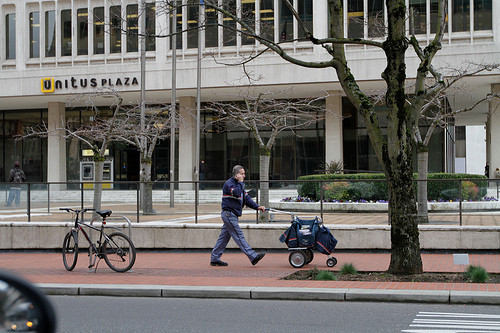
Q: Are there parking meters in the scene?
A: No, there are no parking meters.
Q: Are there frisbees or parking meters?
A: No, there are no parking meters or frisbees.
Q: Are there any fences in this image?
A: Yes, there is a fence.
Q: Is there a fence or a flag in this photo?
A: Yes, there is a fence.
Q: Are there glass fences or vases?
A: Yes, there is a glass fence.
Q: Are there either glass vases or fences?
A: Yes, there is a glass fence.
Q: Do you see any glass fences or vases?
A: Yes, there is a glass fence.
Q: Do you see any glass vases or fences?
A: Yes, there is a glass fence.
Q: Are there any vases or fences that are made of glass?
A: Yes, the fence is made of glass.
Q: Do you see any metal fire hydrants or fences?
A: Yes, there is a metal fence.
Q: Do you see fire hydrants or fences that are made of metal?
A: Yes, the fence is made of metal.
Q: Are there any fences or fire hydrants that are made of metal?
A: Yes, the fence is made of metal.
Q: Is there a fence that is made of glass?
A: Yes, there is a fence that is made of glass.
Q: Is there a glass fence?
A: Yes, there is a fence that is made of glass.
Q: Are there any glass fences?
A: Yes, there is a fence that is made of glass.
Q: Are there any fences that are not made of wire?
A: Yes, there is a fence that is made of glass.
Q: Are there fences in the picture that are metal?
A: Yes, there is a metal fence.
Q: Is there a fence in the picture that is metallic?
A: Yes, there is a fence that is metallic.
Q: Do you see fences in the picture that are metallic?
A: Yes, there is a fence that is metallic.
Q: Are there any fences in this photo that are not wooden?
A: Yes, there is a metallic fence.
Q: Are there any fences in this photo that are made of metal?
A: Yes, there is a fence that is made of metal.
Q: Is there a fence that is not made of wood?
A: Yes, there is a fence that is made of metal.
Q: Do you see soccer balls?
A: No, there are no soccer balls.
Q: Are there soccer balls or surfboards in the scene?
A: No, there are no soccer balls or surfboards.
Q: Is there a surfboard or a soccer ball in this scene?
A: No, there are no soccer balls or surfboards.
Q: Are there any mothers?
A: No, there are no mothers.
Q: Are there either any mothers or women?
A: No, there are no mothers or women.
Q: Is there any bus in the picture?
A: No, there are no buses.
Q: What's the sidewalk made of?
A: The sidewalk is made of brick.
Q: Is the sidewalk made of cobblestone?
A: No, the sidewalk is made of brick.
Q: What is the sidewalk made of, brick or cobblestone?
A: The sidewalk is made of brick.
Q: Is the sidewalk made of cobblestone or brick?
A: The sidewalk is made of brick.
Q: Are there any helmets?
A: No, there are no helmets.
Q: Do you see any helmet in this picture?
A: No, there are no helmets.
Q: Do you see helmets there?
A: No, there are no helmets.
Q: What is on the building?
A: The sign is on the building.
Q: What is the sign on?
A: The sign is on the building.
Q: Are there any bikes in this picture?
A: Yes, there is a bike.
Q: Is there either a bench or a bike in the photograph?
A: Yes, there is a bike.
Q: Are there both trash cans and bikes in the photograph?
A: No, there is a bike but no trash cans.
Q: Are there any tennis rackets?
A: No, there are no tennis rackets.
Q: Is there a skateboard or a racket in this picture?
A: No, there are no rackets or skateboards.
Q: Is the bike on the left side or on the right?
A: The bike is on the left of the image.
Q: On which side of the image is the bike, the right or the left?
A: The bike is on the left of the image.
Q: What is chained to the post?
A: The bike is chained to the post.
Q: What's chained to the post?
A: The bike is chained to the post.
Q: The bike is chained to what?
A: The bike is chained to the post.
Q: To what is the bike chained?
A: The bike is chained to the post.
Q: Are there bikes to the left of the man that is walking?
A: Yes, there is a bike to the left of the man.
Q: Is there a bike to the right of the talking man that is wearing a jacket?
A: No, the bike is to the left of the man.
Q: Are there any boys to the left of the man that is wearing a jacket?
A: No, there is a bike to the left of the man.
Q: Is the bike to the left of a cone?
A: No, the bike is to the left of the man.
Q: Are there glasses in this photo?
A: No, there are no glasses.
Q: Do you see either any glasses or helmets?
A: No, there are no glasses or helmets.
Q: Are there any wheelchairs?
A: No, there are no wheelchairs.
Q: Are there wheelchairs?
A: No, there are no wheelchairs.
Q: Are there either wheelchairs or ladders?
A: No, there are no wheelchairs or ladders.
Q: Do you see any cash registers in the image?
A: No, there are no cash registers.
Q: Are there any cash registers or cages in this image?
A: No, there are no cash registers or cages.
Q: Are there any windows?
A: Yes, there are windows.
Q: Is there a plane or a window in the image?
A: Yes, there are windows.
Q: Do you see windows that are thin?
A: Yes, there are thin windows.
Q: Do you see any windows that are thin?
A: Yes, there are windows that are thin.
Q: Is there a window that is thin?
A: Yes, there are windows that are thin.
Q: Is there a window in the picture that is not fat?
A: Yes, there are thin windows.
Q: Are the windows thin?
A: Yes, the windows are thin.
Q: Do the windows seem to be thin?
A: Yes, the windows are thin.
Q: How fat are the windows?
A: The windows are thin.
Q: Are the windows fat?
A: No, the windows are thin.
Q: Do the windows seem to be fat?
A: No, the windows are thin.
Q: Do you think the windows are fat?
A: No, the windows are thin.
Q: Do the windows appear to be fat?
A: No, the windows are thin.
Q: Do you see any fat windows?
A: No, there are windows but they are thin.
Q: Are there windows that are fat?
A: No, there are windows but they are thin.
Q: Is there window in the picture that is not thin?
A: No, there are windows but they are thin.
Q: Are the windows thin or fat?
A: The windows are thin.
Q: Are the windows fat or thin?
A: The windows are thin.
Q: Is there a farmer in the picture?
A: No, there are no farmers.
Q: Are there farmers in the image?
A: No, there are no farmers.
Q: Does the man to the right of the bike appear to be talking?
A: Yes, the man is talking.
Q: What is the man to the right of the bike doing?
A: The man is talking.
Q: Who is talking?
A: The man is talking.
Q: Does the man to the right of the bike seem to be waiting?
A: No, the man is talking.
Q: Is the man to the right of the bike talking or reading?
A: The man is talking.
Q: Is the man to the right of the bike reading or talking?
A: The man is talking.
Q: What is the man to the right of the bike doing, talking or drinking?
A: The man is talking.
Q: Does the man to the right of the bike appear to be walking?
A: Yes, the man is walking.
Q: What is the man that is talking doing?
A: The man is walking.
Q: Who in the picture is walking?
A: The man is walking.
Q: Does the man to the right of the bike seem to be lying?
A: No, the man is walking.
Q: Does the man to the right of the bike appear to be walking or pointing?
A: The man is walking.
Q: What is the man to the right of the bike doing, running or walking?
A: The man is walking.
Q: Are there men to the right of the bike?
A: Yes, there is a man to the right of the bike.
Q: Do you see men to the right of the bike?
A: Yes, there is a man to the right of the bike.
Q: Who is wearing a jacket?
A: The man is wearing a jacket.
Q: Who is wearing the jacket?
A: The man is wearing a jacket.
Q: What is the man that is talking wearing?
A: The man is wearing a jacket.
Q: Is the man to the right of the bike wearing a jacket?
A: Yes, the man is wearing a jacket.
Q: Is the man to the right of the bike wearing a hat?
A: No, the man is wearing a jacket.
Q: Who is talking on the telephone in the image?
A: The man is talking on the telephone.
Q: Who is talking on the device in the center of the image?
A: The man is talking on the telephone.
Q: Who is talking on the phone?
A: The man is talking on the telephone.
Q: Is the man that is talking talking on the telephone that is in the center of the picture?
A: Yes, the man is talking on the telephone.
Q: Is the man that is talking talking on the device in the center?
A: Yes, the man is talking on the telephone.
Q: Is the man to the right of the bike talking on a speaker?
A: No, the man is talking on the telephone.